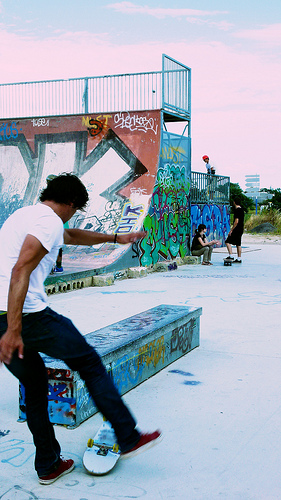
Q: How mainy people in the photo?
A: 3.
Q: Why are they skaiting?
A: To have fun.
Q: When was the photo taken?
A: Day time.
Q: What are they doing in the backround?
A: Talking.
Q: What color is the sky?
A: Pink.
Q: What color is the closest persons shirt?
A: White.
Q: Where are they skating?
A: Skate park.